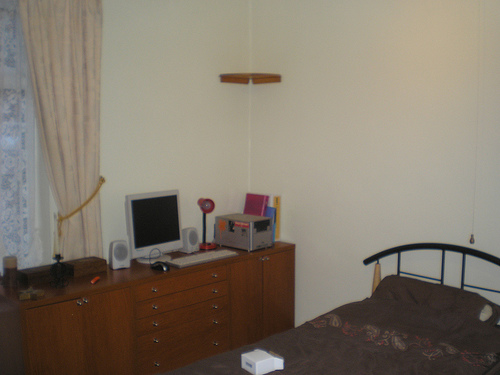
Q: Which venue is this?
A: This is a bedroom.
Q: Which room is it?
A: It is a bedroom.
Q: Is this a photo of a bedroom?
A: Yes, it is showing a bedroom.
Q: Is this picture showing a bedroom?
A: Yes, it is showing a bedroom.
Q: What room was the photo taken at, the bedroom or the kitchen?
A: It was taken at the bedroom.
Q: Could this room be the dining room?
A: No, it is the bedroom.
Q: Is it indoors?
A: Yes, it is indoors.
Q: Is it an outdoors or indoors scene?
A: It is indoors.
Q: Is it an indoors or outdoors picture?
A: It is indoors.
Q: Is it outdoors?
A: No, it is indoors.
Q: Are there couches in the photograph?
A: No, there are no couches.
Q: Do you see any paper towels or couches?
A: No, there are no couches or paper towels.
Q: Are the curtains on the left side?
A: Yes, the curtains are on the left of the image.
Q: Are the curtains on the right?
A: No, the curtains are on the left of the image.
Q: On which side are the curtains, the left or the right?
A: The curtains are on the left of the image.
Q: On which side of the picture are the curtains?
A: The curtains are on the left of the image.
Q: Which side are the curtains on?
A: The curtains are on the left of the image.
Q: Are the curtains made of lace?
A: Yes, the curtains are made of lace.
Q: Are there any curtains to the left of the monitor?
A: Yes, there are curtains to the left of the monitor.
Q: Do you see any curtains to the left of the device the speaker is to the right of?
A: Yes, there are curtains to the left of the monitor.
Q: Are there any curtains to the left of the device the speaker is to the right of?
A: Yes, there are curtains to the left of the monitor.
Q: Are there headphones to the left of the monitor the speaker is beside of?
A: No, there are curtains to the left of the monitor.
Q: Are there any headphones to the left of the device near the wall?
A: No, there are curtains to the left of the monitor.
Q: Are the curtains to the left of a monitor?
A: Yes, the curtains are to the left of a monitor.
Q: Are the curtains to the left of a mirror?
A: No, the curtains are to the left of a monitor.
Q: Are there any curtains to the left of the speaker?
A: Yes, there are curtains to the left of the speaker.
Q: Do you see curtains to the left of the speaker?
A: Yes, there are curtains to the left of the speaker.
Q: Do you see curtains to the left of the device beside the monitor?
A: Yes, there are curtains to the left of the speaker.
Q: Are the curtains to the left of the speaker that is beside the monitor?
A: Yes, the curtains are to the left of the speaker.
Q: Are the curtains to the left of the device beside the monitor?
A: Yes, the curtains are to the left of the speaker.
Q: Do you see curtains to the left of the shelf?
A: Yes, there are curtains to the left of the shelf.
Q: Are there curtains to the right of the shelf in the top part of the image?
A: No, the curtains are to the left of the shelf.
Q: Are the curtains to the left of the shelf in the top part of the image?
A: Yes, the curtains are to the left of the shelf.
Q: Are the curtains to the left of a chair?
A: No, the curtains are to the left of the shelf.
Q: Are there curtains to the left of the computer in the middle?
A: Yes, there are curtains to the left of the computer.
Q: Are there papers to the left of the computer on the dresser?
A: No, there are curtains to the left of the computer.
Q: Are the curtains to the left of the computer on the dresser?
A: Yes, the curtains are to the left of the computer.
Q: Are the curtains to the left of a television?
A: No, the curtains are to the left of the computer.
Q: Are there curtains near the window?
A: Yes, there are curtains near the window.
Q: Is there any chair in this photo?
A: No, there are no chairs.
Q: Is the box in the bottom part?
A: Yes, the box is in the bottom of the image.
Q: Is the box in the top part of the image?
A: No, the box is in the bottom of the image.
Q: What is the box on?
A: The box is on the bed.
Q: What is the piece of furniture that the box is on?
A: The piece of furniture is a bed.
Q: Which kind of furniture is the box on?
A: The box is on the bed.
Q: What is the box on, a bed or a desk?
A: The box is on a bed.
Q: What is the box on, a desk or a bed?
A: The box is on a bed.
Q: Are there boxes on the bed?
A: Yes, there is a box on the bed.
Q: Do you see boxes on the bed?
A: Yes, there is a box on the bed.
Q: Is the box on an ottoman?
A: No, the box is on a bed.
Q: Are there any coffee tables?
A: No, there are no coffee tables.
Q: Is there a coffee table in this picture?
A: No, there are no coffee tables.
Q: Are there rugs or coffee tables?
A: No, there are no coffee tables or rugs.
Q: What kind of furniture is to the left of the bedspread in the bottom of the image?
A: The piece of furniture is a dresser.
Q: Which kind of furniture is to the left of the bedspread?
A: The piece of furniture is a dresser.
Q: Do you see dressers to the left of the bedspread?
A: Yes, there is a dresser to the left of the bedspread.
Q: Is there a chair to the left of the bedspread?
A: No, there is a dresser to the left of the bedspread.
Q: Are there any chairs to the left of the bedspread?
A: No, there is a dresser to the left of the bedspread.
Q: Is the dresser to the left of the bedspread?
A: Yes, the dresser is to the left of the bedspread.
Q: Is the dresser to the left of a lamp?
A: No, the dresser is to the left of the bedspread.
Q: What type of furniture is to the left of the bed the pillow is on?
A: The piece of furniture is a dresser.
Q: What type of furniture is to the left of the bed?
A: The piece of furniture is a dresser.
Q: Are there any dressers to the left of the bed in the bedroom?
A: Yes, there is a dresser to the left of the bed.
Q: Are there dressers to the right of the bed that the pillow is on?
A: No, the dresser is to the left of the bed.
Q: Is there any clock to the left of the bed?
A: No, there is a dresser to the left of the bed.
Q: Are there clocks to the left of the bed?
A: No, there is a dresser to the left of the bed.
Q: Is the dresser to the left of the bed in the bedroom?
A: Yes, the dresser is to the left of the bed.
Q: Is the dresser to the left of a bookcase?
A: No, the dresser is to the left of the bed.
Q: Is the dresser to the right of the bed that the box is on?
A: No, the dresser is to the left of the bed.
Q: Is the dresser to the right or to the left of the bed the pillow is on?
A: The dresser is to the left of the bed.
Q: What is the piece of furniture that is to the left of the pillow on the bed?
A: The piece of furniture is a dresser.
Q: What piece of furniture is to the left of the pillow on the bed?
A: The piece of furniture is a dresser.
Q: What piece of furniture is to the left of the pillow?
A: The piece of furniture is a dresser.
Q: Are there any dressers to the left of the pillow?
A: Yes, there is a dresser to the left of the pillow.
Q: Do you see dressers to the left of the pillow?
A: Yes, there is a dresser to the left of the pillow.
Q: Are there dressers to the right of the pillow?
A: No, the dresser is to the left of the pillow.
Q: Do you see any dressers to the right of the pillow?
A: No, the dresser is to the left of the pillow.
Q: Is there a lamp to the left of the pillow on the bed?
A: No, there is a dresser to the left of the pillow.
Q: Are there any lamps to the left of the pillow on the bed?
A: No, there is a dresser to the left of the pillow.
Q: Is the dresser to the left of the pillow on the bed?
A: Yes, the dresser is to the left of the pillow.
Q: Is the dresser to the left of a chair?
A: No, the dresser is to the left of the pillow.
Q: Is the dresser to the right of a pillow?
A: No, the dresser is to the left of a pillow.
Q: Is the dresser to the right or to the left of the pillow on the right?
A: The dresser is to the left of the pillow.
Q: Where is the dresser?
A: The dresser is in the bedroom.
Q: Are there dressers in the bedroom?
A: Yes, there is a dresser in the bedroom.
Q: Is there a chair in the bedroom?
A: No, there is a dresser in the bedroom.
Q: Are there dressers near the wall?
A: Yes, there is a dresser near the wall.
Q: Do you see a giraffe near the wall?
A: No, there is a dresser near the wall.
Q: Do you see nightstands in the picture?
A: No, there are no nightstands.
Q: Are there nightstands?
A: No, there are no nightstands.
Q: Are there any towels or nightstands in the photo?
A: No, there are no nightstands or towels.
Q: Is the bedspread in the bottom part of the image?
A: Yes, the bedspread is in the bottom of the image.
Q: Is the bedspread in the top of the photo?
A: No, the bedspread is in the bottom of the image.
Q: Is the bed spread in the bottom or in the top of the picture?
A: The bed spread is in the bottom of the image.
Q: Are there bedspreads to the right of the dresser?
A: Yes, there is a bedspread to the right of the dresser.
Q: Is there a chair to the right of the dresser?
A: No, there is a bedspread to the right of the dresser.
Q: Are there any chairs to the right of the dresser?
A: No, there is a bedspread to the right of the dresser.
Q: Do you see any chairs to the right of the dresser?
A: No, there is a bedspread to the right of the dresser.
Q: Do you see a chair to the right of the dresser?
A: No, there is a bedspread to the right of the dresser.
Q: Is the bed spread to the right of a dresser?
A: Yes, the bed spread is to the right of a dresser.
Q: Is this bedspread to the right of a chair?
A: No, the bedspread is to the right of a dresser.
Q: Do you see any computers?
A: Yes, there is a computer.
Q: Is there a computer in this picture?
A: Yes, there is a computer.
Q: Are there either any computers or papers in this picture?
A: Yes, there is a computer.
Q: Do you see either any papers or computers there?
A: Yes, there is a computer.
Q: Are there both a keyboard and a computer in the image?
A: Yes, there are both a computer and a keyboard.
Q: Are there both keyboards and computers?
A: Yes, there are both a computer and a keyboard.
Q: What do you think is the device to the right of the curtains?
A: The device is a computer.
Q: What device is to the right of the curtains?
A: The device is a computer.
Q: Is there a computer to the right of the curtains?
A: Yes, there is a computer to the right of the curtains.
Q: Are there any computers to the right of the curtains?
A: Yes, there is a computer to the right of the curtains.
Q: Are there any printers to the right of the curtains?
A: No, there is a computer to the right of the curtains.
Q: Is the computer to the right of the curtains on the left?
A: Yes, the computer is to the right of the curtains.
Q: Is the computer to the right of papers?
A: No, the computer is to the right of the curtains.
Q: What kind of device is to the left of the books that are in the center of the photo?
A: The device is a computer.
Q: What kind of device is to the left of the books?
A: The device is a computer.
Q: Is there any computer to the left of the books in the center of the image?
A: Yes, there is a computer to the left of the books.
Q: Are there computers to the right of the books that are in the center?
A: No, the computer is to the left of the books.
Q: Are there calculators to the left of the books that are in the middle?
A: No, there is a computer to the left of the books.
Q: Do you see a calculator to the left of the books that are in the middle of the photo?
A: No, there is a computer to the left of the books.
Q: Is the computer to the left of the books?
A: Yes, the computer is to the left of the books.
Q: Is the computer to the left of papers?
A: No, the computer is to the left of the books.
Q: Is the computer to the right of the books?
A: No, the computer is to the left of the books.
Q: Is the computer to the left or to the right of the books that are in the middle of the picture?
A: The computer is to the left of the books.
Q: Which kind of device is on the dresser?
A: The device is a computer.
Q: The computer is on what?
A: The computer is on the dresser.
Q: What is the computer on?
A: The computer is on the dresser.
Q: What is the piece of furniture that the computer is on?
A: The piece of furniture is a dresser.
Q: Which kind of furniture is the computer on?
A: The computer is on the dresser.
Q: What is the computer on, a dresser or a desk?
A: The computer is on a dresser.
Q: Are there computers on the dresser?
A: Yes, there is a computer on the dresser.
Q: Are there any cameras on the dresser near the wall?
A: No, there is a computer on the dresser.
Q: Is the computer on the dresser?
A: Yes, the computer is on the dresser.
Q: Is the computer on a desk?
A: No, the computer is on the dresser.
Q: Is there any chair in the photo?
A: No, there are no chairs.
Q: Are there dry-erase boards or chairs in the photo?
A: No, there are no chairs or dry-erase boards.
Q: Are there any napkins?
A: No, there are no napkins.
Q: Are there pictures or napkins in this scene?
A: No, there are no napkins or pictures.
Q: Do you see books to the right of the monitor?
A: Yes, there are books to the right of the monitor.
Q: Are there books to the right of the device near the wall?
A: Yes, there are books to the right of the monitor.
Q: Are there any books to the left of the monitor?
A: No, the books are to the right of the monitor.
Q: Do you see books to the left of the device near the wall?
A: No, the books are to the right of the monitor.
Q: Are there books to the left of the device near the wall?
A: No, the books are to the right of the monitor.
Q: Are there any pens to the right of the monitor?
A: No, there are books to the right of the monitor.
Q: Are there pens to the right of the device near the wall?
A: No, there are books to the right of the monitor.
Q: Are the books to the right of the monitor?
A: Yes, the books are to the right of the monitor.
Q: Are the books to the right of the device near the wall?
A: Yes, the books are to the right of the monitor.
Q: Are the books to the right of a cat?
A: No, the books are to the right of the monitor.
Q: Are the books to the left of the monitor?
A: No, the books are to the right of the monitor.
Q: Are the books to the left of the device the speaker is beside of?
A: No, the books are to the right of the monitor.